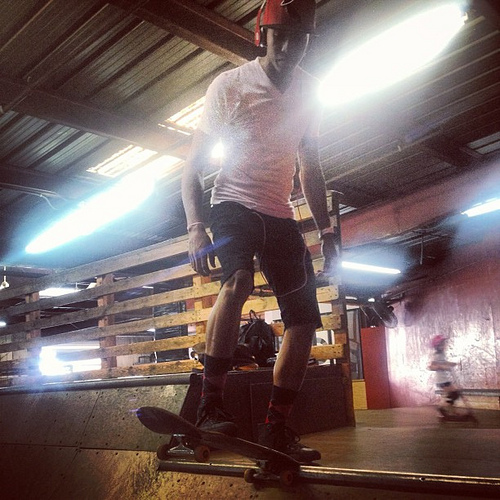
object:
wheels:
[157, 443, 210, 463]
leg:
[201, 253, 254, 398]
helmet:
[253, 0, 318, 48]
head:
[254, 1, 317, 76]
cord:
[229, 200, 308, 298]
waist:
[209, 161, 296, 221]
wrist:
[315, 220, 335, 242]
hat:
[254, 0, 317, 48]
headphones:
[254, 0, 266, 48]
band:
[187, 222, 204, 233]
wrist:
[183, 204, 208, 236]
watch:
[318, 226, 338, 241]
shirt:
[195, 56, 323, 220]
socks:
[201, 352, 300, 424]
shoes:
[195, 354, 321, 463]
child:
[427, 334, 478, 427]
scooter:
[437, 360, 479, 427]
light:
[23, 176, 156, 257]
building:
[0, 0, 500, 500]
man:
[136, 0, 339, 484]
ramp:
[0, 371, 500, 500]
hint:
[136, 406, 304, 487]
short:
[208, 200, 324, 332]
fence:
[0, 190, 350, 389]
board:
[135, 405, 302, 487]